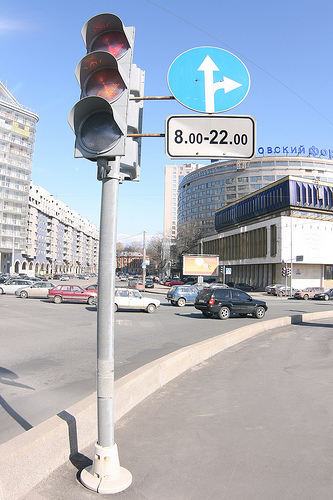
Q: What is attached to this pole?
A: Traffic light.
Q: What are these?
A: Signs.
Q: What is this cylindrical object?
A: Pole.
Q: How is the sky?
A: Clear blue.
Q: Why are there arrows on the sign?
A: To show directions?.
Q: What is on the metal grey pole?
A: Traffic lights.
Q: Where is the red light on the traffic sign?
A: On the top of the yellow light.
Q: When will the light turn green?
A: After the yellow is on.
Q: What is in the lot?
A: Automobiles.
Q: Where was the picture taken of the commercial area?
A: Foreign country.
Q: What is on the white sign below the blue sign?
A: 8.00-22.00.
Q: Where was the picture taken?
A: On a street.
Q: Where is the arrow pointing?
A: Straight and right.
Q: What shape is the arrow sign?
A: Circle.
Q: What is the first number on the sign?
A: 8.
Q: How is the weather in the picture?
A: Sunny.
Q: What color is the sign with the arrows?
A: Blue.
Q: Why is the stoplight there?
A: So people know when to drive.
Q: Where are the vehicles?
A: In the parking lot.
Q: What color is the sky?
A: Blue.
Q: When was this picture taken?
A: Daytime.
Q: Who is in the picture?
A: Nobody.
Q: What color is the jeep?
A: Black.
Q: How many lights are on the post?
A: Three.